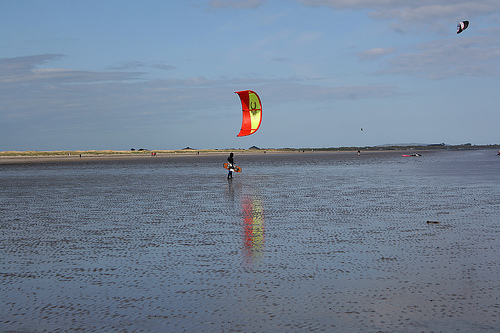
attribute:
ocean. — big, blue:
[3, 175, 497, 330]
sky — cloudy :
[17, 7, 477, 129]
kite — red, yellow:
[233, 88, 263, 137]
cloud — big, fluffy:
[351, 45, 403, 60]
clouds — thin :
[10, 57, 265, 131]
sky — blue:
[0, 0, 498, 147]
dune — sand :
[175, 143, 213, 158]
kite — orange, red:
[236, 89, 265, 139]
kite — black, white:
[454, 17, 468, 34]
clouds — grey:
[90, 73, 159, 136]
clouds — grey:
[4, 49, 93, 147]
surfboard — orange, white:
[221, 156, 244, 177]